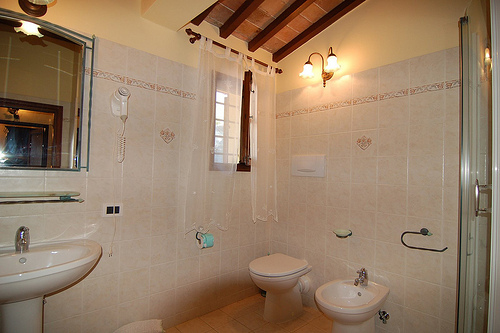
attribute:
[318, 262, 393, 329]
bidet — white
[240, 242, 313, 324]
toilet — white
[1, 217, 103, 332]
sink — white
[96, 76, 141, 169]
dryer — white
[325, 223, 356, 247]
holder — white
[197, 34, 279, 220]
curtains — white, translucent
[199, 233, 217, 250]
paper — green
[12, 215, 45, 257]
faucet — silver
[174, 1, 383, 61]
ceiling — brown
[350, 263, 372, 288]
faucet — silver